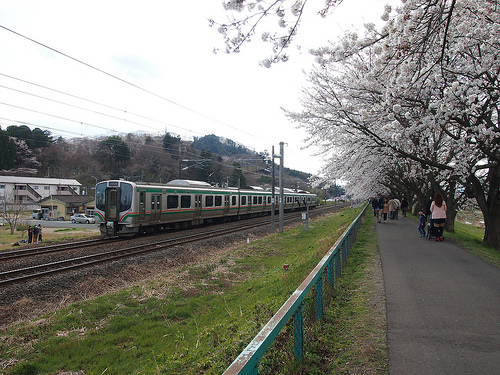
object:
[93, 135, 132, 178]
trees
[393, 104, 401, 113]
flowers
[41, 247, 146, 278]
train tracks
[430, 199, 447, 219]
blazer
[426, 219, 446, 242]
baby stroller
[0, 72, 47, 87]
power lines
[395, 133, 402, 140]
white flowers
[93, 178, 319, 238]
passenger train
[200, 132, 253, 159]
mountain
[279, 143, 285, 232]
pole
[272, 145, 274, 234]
pole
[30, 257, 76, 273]
railway tracks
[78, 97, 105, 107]
powerlines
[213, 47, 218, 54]
cherry blossom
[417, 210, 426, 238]
people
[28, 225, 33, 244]
people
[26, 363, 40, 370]
grass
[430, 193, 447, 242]
lady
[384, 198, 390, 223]
pedestrians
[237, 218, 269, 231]
train track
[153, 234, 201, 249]
train track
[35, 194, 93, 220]
building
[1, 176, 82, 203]
apartment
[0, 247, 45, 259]
tracks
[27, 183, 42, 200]
staircase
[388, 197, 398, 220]
people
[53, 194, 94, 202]
roof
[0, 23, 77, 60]
lines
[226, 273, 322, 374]
fence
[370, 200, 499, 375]
path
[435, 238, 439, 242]
shoes